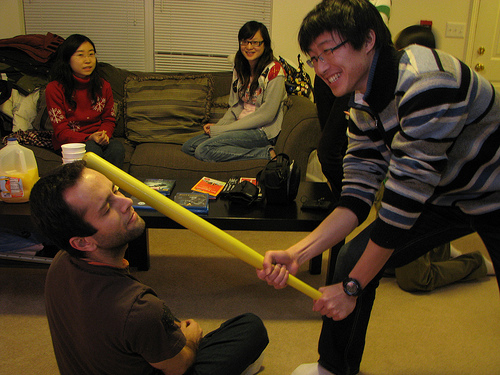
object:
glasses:
[304, 38, 352, 65]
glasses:
[240, 39, 265, 46]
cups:
[61, 143, 87, 164]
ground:
[406, 294, 487, 360]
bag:
[256, 154, 303, 211]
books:
[114, 178, 176, 211]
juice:
[0, 138, 40, 204]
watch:
[342, 275, 366, 299]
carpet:
[0, 226, 500, 375]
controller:
[219, 176, 242, 196]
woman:
[43, 34, 126, 178]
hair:
[55, 34, 104, 112]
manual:
[191, 176, 227, 196]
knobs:
[475, 63, 485, 73]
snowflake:
[48, 107, 64, 123]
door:
[465, 0, 500, 93]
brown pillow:
[125, 74, 217, 144]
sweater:
[44, 75, 117, 149]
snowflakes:
[91, 96, 107, 112]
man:
[29, 160, 269, 375]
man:
[258, 0, 500, 375]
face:
[305, 29, 360, 97]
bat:
[81, 150, 323, 301]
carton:
[0, 138, 41, 203]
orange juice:
[0, 175, 24, 198]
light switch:
[444, 22, 465, 39]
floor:
[0, 202, 498, 374]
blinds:
[22, 0, 271, 74]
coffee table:
[0, 178, 333, 276]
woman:
[180, 20, 287, 164]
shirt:
[336, 46, 500, 250]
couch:
[0, 71, 320, 222]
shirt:
[43, 251, 186, 375]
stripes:
[126, 78, 211, 142]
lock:
[477, 45, 488, 55]